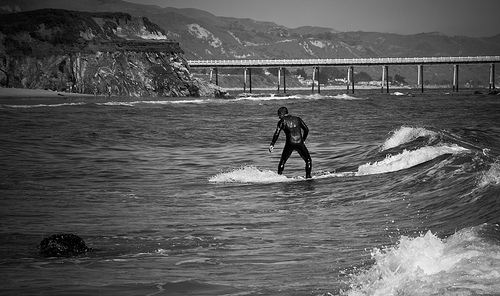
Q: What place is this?
A: It is an ocean.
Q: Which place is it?
A: It is an ocean.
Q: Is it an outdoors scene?
A: Yes, it is outdoors.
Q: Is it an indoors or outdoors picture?
A: It is outdoors.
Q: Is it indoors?
A: No, it is outdoors.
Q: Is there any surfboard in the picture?
A: Yes, there is a surfboard.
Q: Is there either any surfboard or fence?
A: Yes, there is a surfboard.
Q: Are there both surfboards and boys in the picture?
A: No, there is a surfboard but no boys.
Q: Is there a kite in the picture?
A: No, there are no kites.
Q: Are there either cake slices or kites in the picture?
A: No, there are no kites or cake slices.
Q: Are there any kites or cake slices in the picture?
A: No, there are no kites or cake slices.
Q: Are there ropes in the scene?
A: No, there are no ropes.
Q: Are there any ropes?
A: No, there are no ropes.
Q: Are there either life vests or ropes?
A: No, there are no ropes or life vests.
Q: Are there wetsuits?
A: Yes, there is a wetsuit.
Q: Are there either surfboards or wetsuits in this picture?
A: Yes, there is a wetsuit.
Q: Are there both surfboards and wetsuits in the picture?
A: Yes, there are both a wetsuit and a surfboard.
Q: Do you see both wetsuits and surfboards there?
A: Yes, there are both a wetsuit and a surfboard.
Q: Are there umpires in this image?
A: No, there are no umpires.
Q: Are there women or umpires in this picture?
A: No, there are no umpires or women.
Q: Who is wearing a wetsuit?
A: The man is wearing a wetsuit.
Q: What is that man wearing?
A: The man is wearing a wetsuit.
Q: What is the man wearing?
A: The man is wearing a wetsuit.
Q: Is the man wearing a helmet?
A: No, the man is wearing a wetsuit.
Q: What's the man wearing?
A: The man is wearing a wetsuit.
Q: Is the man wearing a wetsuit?
A: Yes, the man is wearing a wetsuit.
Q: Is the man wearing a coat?
A: No, the man is wearing a wetsuit.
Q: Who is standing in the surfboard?
A: The man is standing in the surfboard.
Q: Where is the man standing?
A: The man is standing in the surfboard.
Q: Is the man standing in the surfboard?
A: Yes, the man is standing in the surfboard.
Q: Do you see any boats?
A: No, there are no boats.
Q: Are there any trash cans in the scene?
A: No, there are no trash cans.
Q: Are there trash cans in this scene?
A: No, there are no trash cans.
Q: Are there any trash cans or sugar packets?
A: No, there are no trash cans or sugar packets.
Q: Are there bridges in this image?
A: Yes, there is a bridge.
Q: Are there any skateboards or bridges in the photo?
A: Yes, there is a bridge.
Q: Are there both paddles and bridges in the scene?
A: No, there is a bridge but no paddles.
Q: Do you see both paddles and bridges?
A: No, there is a bridge but no paddles.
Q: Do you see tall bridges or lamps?
A: Yes, there is a tall bridge.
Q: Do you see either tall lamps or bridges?
A: Yes, there is a tall bridge.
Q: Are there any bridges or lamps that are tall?
A: Yes, the bridge is tall.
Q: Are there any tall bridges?
A: Yes, there is a tall bridge.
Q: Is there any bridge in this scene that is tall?
A: Yes, there is a bridge that is tall.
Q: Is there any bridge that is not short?
A: Yes, there is a tall bridge.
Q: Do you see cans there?
A: No, there are no cans.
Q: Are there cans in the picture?
A: No, there are no cans.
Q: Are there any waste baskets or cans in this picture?
A: No, there are no cans or waste baskets.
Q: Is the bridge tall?
A: Yes, the bridge is tall.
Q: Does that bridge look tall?
A: Yes, the bridge is tall.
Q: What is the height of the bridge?
A: The bridge is tall.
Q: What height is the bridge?
A: The bridge is tall.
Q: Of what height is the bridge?
A: The bridge is tall.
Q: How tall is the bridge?
A: The bridge is tall.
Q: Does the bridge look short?
A: No, the bridge is tall.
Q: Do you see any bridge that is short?
A: No, there is a bridge but it is tall.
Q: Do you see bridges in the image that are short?
A: No, there is a bridge but it is tall.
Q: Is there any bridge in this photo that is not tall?
A: No, there is a bridge but it is tall.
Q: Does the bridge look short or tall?
A: The bridge is tall.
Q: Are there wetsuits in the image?
A: Yes, there is a wetsuit.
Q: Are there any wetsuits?
A: Yes, there is a wetsuit.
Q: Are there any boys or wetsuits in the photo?
A: Yes, there is a wetsuit.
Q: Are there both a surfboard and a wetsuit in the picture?
A: Yes, there are both a wetsuit and a surfboard.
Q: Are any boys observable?
A: No, there are no boys.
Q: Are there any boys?
A: No, there are no boys.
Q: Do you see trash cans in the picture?
A: No, there are no trash cans.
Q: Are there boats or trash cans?
A: No, there are no trash cans or boats.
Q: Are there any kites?
A: No, there are no kites.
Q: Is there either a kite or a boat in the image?
A: No, there are no kites or boats.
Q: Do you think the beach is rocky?
A: Yes, the beach is rocky.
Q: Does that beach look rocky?
A: Yes, the beach is rocky.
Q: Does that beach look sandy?
A: No, the beach is rocky.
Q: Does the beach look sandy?
A: No, the beach is rocky.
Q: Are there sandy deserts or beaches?
A: No, there is a beach but it is rocky.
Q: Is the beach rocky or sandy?
A: The beach is rocky.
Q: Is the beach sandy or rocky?
A: The beach is rocky.